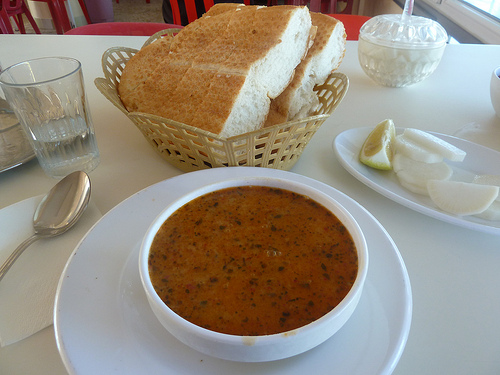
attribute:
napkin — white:
[0, 189, 105, 350]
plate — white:
[60, 152, 415, 367]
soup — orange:
[174, 207, 336, 340]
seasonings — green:
[222, 262, 249, 274]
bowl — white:
[144, 153, 388, 353]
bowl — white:
[134, 172, 367, 363]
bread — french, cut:
[135, 14, 318, 141]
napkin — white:
[2, 204, 52, 341]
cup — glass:
[4, 56, 98, 171]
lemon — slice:
[362, 111, 396, 178]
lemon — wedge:
[356, 117, 396, 169]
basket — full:
[92, 26, 349, 173]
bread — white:
[118, 3, 344, 136]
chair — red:
[53, 2, 233, 38]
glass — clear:
[2, 50, 100, 173]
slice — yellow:
[353, 113, 403, 171]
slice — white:
[419, 173, 499, 218]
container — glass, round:
[351, 0, 458, 94]